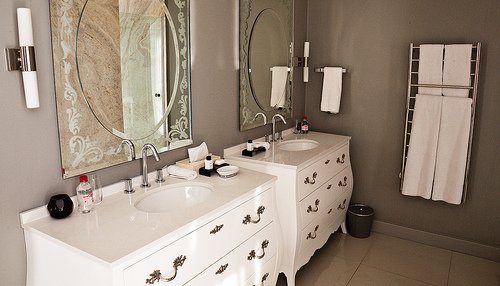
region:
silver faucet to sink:
[133, 146, 158, 181]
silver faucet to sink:
[265, 112, 287, 156]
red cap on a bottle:
[74, 173, 85, 183]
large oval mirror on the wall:
[79, 0, 179, 138]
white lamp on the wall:
[1, 9, 43, 109]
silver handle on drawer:
[240, 205, 276, 224]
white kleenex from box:
[183, 143, 213, 167]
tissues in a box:
[173, 140, 216, 173]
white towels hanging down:
[387, 92, 476, 206]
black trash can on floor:
[339, 204, 381, 235]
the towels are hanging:
[411, 91, 441, 206]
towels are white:
[421, 43, 464, 203]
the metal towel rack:
[401, 45, 488, 216]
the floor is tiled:
[331, 232, 471, 284]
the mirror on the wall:
[46, 8, 196, 157]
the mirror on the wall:
[231, 0, 300, 137]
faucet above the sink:
[126, 137, 176, 192]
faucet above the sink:
[265, 113, 300, 138]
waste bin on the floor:
[343, 201, 378, 237]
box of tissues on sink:
[169, 159, 200, 184]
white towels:
[413, 102, 458, 202]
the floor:
[352, 250, 426, 283]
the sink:
[163, 192, 185, 204]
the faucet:
[139, 140, 164, 163]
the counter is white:
[100, 215, 137, 252]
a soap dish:
[218, 162, 240, 176]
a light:
[12, 8, 52, 110]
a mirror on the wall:
[81, 18, 181, 115]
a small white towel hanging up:
[322, 65, 347, 115]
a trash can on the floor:
[348, 198, 375, 233]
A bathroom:
[2, 0, 492, 283]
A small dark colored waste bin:
[346, 200, 378, 241]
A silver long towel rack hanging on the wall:
[380, 40, 480, 210]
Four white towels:
[412, 33, 467, 205]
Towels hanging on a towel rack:
[398, 33, 480, 213]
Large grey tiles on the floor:
[307, 228, 497, 278]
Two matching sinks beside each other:
[17, 126, 399, 283]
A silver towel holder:
[312, 65, 351, 77]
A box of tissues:
[178, 143, 222, 175]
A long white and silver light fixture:
[7, 5, 50, 115]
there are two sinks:
[11, 95, 464, 270]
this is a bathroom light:
[10, 3, 55, 120]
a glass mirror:
[40, 0, 203, 183]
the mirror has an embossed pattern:
[43, 0, 220, 181]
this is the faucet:
[109, 138, 181, 202]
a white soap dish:
[212, 163, 249, 177]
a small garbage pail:
[347, 195, 387, 242]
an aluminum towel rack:
[382, 31, 498, 222]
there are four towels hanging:
[387, 20, 490, 214]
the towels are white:
[387, 22, 496, 226]